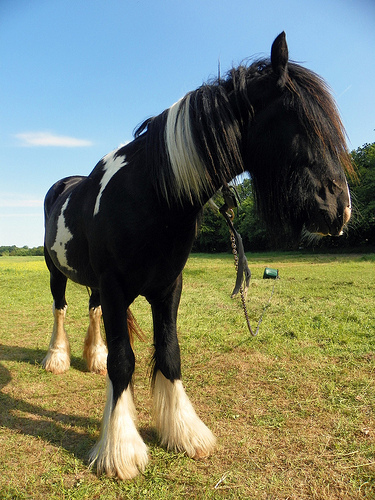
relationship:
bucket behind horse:
[261, 267, 279, 279] [42, 26, 347, 478]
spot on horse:
[45, 197, 79, 264] [42, 26, 347, 478]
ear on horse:
[272, 30, 289, 68] [25, 57, 359, 272]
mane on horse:
[176, 75, 255, 180] [12, 24, 372, 467]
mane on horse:
[197, 75, 255, 110] [42, 26, 347, 478]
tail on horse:
[70, 256, 153, 347] [42, 26, 347, 478]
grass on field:
[1, 255, 373, 497] [2, 253, 370, 495]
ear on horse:
[272, 24, 294, 69] [42, 26, 347, 478]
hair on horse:
[252, 50, 364, 183] [42, 26, 347, 478]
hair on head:
[252, 50, 364, 183] [227, 20, 358, 249]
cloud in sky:
[11, 120, 112, 152] [1, 2, 373, 246]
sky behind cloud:
[1, 2, 373, 50] [16, 127, 92, 157]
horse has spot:
[42, 26, 347, 478] [90, 147, 127, 215]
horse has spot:
[42, 26, 347, 478] [51, 193, 76, 272]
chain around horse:
[196, 140, 302, 314] [41, 58, 367, 311]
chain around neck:
[196, 140, 302, 314] [171, 67, 258, 223]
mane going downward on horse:
[197, 75, 255, 110] [76, 82, 373, 296]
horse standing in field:
[42, 26, 347, 478] [2, 253, 370, 495]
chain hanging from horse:
[215, 176, 279, 338] [42, 26, 347, 478]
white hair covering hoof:
[47, 348, 70, 366] [37, 360, 75, 373]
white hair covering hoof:
[85, 345, 105, 366] [84, 356, 108, 373]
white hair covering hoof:
[96, 433, 145, 462] [85, 455, 159, 480]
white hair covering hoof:
[156, 401, 211, 447] [157, 433, 224, 457]